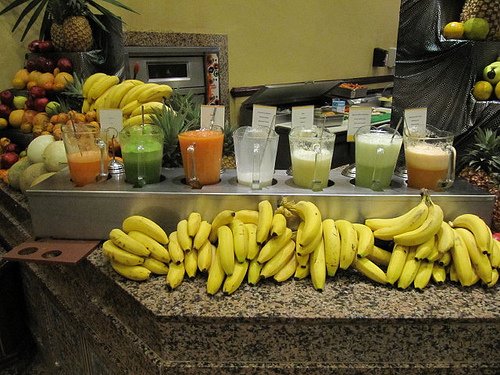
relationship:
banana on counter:
[282, 199, 319, 248] [58, 239, 499, 319]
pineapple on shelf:
[59, 1, 98, 52] [0, 16, 105, 153]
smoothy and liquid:
[289, 151, 334, 190] [183, 131, 225, 186]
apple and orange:
[0, 87, 17, 105] [14, 67, 31, 85]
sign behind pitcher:
[250, 103, 277, 134] [229, 123, 278, 188]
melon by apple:
[45, 141, 76, 175] [0, 87, 17, 105]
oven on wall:
[124, 48, 212, 126] [0, 1, 401, 92]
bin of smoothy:
[27, 164, 496, 241] [289, 151, 334, 190]